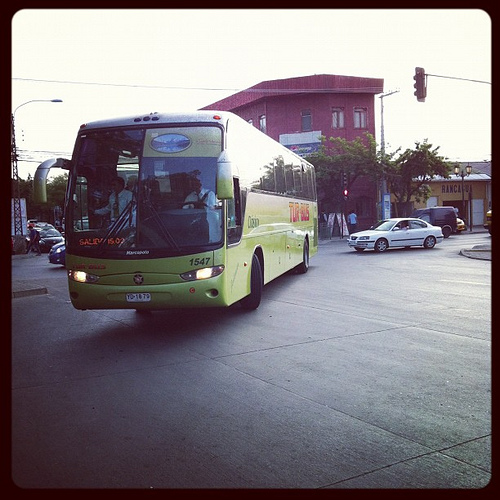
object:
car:
[348, 215, 446, 252]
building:
[194, 74, 382, 239]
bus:
[63, 111, 317, 317]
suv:
[406, 205, 457, 238]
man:
[347, 211, 356, 235]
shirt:
[348, 214, 357, 224]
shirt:
[185, 191, 222, 214]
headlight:
[193, 265, 215, 283]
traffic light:
[414, 68, 500, 102]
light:
[465, 167, 473, 174]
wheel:
[375, 238, 387, 254]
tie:
[113, 195, 120, 220]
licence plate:
[123, 290, 152, 304]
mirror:
[215, 152, 235, 200]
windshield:
[74, 126, 227, 247]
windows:
[354, 111, 361, 129]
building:
[391, 172, 490, 239]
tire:
[239, 254, 262, 310]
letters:
[287, 202, 309, 222]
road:
[13, 255, 496, 496]